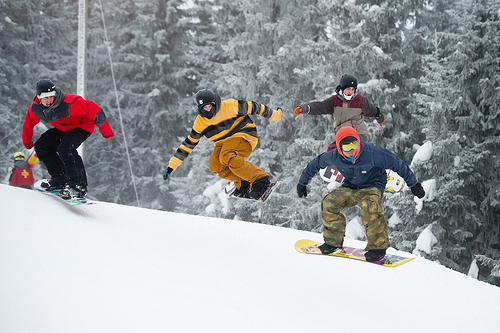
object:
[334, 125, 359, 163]
hat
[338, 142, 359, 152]
goggles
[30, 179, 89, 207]
board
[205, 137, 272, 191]
pants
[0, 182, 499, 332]
snow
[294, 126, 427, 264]
man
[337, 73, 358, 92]
hats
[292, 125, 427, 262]
boy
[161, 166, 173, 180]
glove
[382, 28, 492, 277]
tree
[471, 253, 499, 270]
branch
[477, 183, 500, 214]
branch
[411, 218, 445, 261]
branch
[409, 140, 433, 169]
snow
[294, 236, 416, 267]
board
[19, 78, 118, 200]
person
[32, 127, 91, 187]
pants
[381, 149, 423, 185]
arm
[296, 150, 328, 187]
arm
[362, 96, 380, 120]
arm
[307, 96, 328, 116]
arm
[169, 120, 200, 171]
arm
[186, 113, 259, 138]
shirt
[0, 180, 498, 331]
slope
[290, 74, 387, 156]
person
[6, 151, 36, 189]
person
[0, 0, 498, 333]
ski resort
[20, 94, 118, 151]
clothing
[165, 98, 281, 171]
clothing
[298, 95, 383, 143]
clothing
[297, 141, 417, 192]
clothing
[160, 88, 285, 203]
person